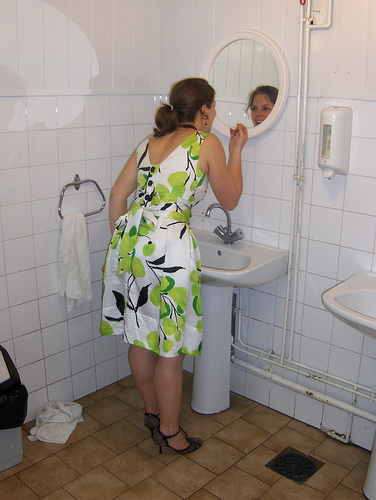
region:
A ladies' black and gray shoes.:
[132, 406, 216, 470]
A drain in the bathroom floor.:
[258, 431, 330, 491]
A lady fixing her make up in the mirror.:
[136, 66, 294, 158]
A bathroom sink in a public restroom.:
[191, 196, 310, 425]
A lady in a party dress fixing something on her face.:
[95, 79, 258, 458]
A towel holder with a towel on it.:
[42, 172, 103, 317]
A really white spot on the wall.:
[3, 2, 106, 156]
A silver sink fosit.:
[198, 200, 251, 249]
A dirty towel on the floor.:
[22, 391, 87, 451]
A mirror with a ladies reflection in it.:
[206, 35, 300, 139]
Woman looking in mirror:
[97, 27, 296, 455]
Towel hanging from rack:
[56, 207, 94, 312]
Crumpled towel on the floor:
[28, 394, 83, 445]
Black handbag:
[0, 344, 29, 432]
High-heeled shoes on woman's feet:
[145, 407, 203, 457]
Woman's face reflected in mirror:
[243, 84, 282, 135]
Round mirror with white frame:
[197, 25, 290, 140]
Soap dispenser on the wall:
[317, 103, 352, 182]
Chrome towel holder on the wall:
[56, 175, 106, 220]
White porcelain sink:
[188, 205, 294, 413]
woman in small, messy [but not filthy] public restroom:
[0, 0, 374, 497]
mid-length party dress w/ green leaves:
[90, 125, 219, 358]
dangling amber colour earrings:
[200, 116, 209, 129]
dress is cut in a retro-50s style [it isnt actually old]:
[91, 126, 218, 358]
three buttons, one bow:
[105, 161, 190, 279]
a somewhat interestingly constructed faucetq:
[202, 197, 249, 247]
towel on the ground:
[25, 396, 91, 450]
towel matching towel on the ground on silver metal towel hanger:
[47, 170, 109, 321]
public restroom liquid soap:
[312, 104, 357, 188]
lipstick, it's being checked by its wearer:
[153, 75, 287, 134]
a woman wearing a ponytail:
[134, 58, 239, 150]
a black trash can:
[0, 344, 37, 466]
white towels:
[24, 384, 91, 445]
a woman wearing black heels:
[119, 0, 218, 457]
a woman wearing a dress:
[108, 96, 206, 356]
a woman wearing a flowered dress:
[98, 61, 244, 345]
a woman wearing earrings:
[155, 68, 223, 143]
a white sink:
[157, 203, 263, 423]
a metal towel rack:
[48, 163, 126, 306]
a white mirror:
[187, 18, 289, 161]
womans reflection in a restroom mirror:
[241, 82, 278, 128]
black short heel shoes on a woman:
[141, 411, 202, 456]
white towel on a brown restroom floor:
[25, 398, 85, 444]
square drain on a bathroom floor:
[262, 443, 326, 484]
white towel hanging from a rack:
[55, 211, 95, 311]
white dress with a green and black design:
[96, 130, 214, 358]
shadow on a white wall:
[1, 0, 100, 132]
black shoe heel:
[158, 443, 164, 456]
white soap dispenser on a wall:
[315, 103, 354, 180]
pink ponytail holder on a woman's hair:
[167, 102, 176, 110]